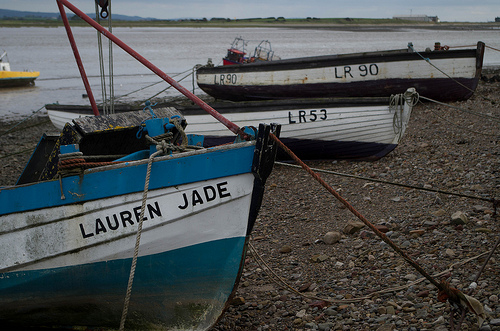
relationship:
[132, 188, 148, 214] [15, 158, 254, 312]
rope hanging off boat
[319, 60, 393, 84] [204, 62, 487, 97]
lr90 on boat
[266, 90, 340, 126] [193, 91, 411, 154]
lr 53 on boat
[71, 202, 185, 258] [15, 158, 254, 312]
lauren on boat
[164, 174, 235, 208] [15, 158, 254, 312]
jade on boat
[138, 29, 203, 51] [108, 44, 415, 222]
water behind boats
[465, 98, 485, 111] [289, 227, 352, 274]
rocks on ground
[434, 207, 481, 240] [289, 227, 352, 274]
rock on ground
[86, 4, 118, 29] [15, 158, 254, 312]
grommot on boat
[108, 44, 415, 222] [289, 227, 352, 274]
boats on ground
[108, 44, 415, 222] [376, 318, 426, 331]
boats on land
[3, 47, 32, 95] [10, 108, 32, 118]
boat on shore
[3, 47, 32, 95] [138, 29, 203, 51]
boat in water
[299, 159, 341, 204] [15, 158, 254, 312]
red rope on boat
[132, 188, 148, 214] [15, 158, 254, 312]
rope attached to boat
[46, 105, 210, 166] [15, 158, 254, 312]
rope holder on boat